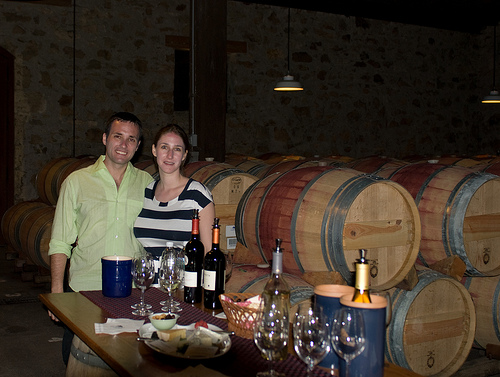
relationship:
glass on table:
[124, 242, 165, 324] [36, 257, 425, 374]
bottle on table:
[185, 208, 202, 303] [38, 287, 425, 374]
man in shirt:
[36, 109, 158, 294] [40, 155, 157, 289]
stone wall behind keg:
[297, 33, 446, 150] [296, 163, 411, 285]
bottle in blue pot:
[353, 247, 372, 302] [334, 291, 389, 374]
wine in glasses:
[181, 209, 223, 304] [330, 310, 361, 369]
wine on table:
[200, 215, 232, 310] [34, 277, 313, 375]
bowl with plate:
[144, 302, 177, 329] [137, 308, 225, 361]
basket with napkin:
[216, 289, 269, 339] [217, 291, 264, 322]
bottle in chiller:
[347, 243, 379, 323] [334, 284, 391, 374]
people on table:
[60, 117, 222, 284] [59, 293, 123, 347]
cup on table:
[100, 252, 136, 299] [36, 257, 425, 374]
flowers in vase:
[149, 297, 251, 356] [75, 247, 134, 302]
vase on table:
[102, 253, 130, 296] [37, 279, 389, 375]